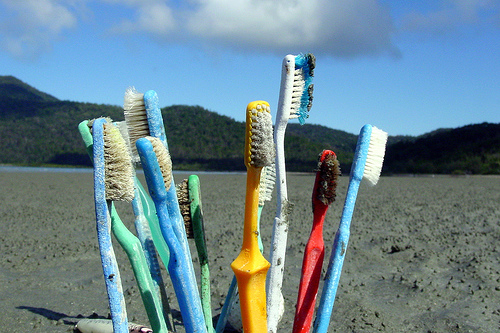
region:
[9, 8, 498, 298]
toothbrushes standing on the beach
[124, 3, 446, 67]
small low cumulus cloud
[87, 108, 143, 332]
light blue toothbrush with white speckles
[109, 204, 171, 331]
light blue-green toothbrush handle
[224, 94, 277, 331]
yellow toothbrush with gray bristles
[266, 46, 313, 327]
white toothbrush with wet sand on its bristles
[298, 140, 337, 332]
red toothbrush with dark bristles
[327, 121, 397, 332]
light blue toothbrush with white bristles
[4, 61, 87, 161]
forested hill near a beach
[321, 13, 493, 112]
blue sky with small clouds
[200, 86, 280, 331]
orange tooth brush.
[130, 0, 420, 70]
a gray cloud.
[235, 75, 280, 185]
bristles on a toothbrush.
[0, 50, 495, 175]
a small mountain range.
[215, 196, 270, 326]
handle on a yellow toothbrush.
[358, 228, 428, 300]
clump of rocks on sand.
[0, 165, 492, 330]
sand covered area.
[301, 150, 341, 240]
dirty tooth brush bristles.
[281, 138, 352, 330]
large red toothbrush next to many others.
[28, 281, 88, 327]
a dark shadow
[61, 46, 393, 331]
toothbrushes in the sand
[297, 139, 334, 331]
dirty red colored toothbrush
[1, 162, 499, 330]
large area of sand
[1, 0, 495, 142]
blue cloudy sky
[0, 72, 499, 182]
hilly area in the distance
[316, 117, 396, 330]
toothbrush farthest to the right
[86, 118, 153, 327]
toothbrush on the left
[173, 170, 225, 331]
the shortest toothbrush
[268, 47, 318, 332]
tall white colored toothbrush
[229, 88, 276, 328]
dirty yellow toothbrush in the sand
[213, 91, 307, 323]
the toothbrush is yellow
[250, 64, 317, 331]
the toothbrush is yellow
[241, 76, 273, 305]
the toothbrush is yellow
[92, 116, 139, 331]
a used blue toothbrush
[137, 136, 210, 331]
a used blue toothbrush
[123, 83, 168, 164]
a used blue toothbrush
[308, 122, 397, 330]
a used blue toothbrush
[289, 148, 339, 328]
a used red toothbrush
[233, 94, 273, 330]
a used yellow toothbrush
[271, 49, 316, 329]
a used white toothbrush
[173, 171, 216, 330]
a used green toothbrush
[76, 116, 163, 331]
a used green toothbrush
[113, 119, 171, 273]
a used green toothbrush